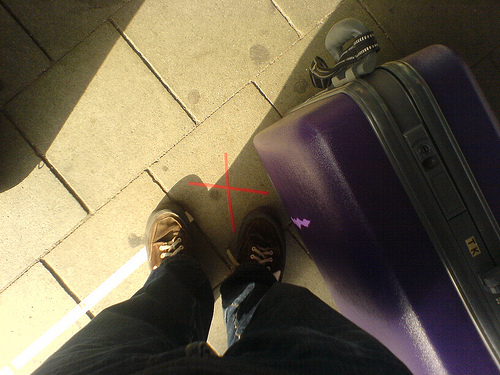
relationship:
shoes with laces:
[138, 197, 293, 299] [153, 226, 278, 271]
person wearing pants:
[27, 192, 397, 372] [27, 266, 407, 373]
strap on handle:
[309, 31, 380, 88] [290, 0, 403, 70]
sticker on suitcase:
[462, 234, 483, 254] [267, 21, 498, 369]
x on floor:
[185, 149, 269, 234] [10, 5, 489, 373]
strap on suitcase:
[302, 31, 395, 90] [247, 29, 494, 371]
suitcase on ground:
[247, 29, 494, 371] [4, 7, 471, 349]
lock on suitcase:
[409, 132, 442, 171] [247, 29, 494, 371]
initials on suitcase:
[464, 234, 484, 255] [267, 21, 498, 369]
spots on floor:
[178, 37, 318, 108] [10, 5, 489, 373]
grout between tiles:
[2, 110, 89, 215] [4, 4, 425, 374]